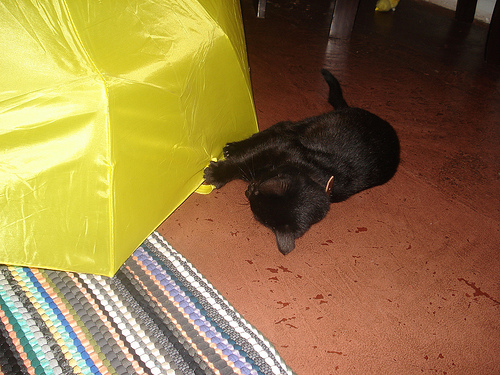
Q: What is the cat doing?
A: Playing.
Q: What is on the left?
A: Carpet.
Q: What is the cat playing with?
A: Umbrella.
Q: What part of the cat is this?
A: Back.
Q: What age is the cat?
A: Kitten.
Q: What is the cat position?
A: On its side.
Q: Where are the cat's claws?
A: On the umbrella.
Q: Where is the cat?
A: On the floor.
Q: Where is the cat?
A: On the floor.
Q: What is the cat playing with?
A: Umbrella.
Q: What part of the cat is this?
A: Head.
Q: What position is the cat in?
A: Lying.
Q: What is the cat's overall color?
A: Black.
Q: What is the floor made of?
A: Clay.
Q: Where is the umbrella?
A: On the floor.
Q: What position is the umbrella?
A: Open.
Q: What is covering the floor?
A: Rug.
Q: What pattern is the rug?
A: Striped.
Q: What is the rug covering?
A: Floor.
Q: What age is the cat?
A: Kitten.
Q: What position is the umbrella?
A: Open.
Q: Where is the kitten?
A: On the floor.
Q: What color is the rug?
A: Multi.